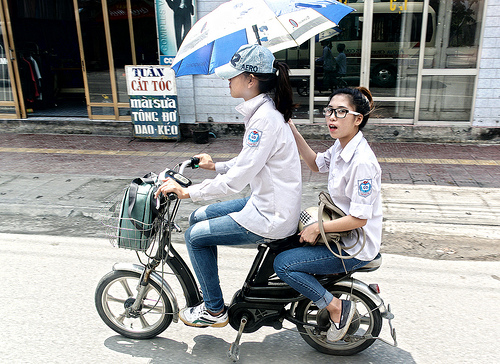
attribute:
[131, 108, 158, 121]
letter — white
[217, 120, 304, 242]
shirt — white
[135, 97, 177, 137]
letter — white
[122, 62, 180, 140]
sign — white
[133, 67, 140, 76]
letter — white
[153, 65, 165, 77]
letter — white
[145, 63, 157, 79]
letter — white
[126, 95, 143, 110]
letter — white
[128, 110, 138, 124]
letter — white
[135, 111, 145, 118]
letter — white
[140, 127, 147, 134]
letter — white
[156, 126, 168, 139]
letter — white